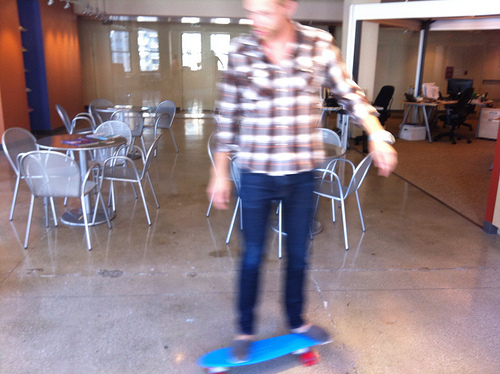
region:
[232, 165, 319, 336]
pair of blue jeans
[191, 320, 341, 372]
blue skateboard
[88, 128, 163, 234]
silver straight back chair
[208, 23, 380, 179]
brown and white plaid long sleeve shirt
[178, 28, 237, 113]
two windows on white doors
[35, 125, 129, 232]
round silver table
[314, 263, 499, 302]
tan square shaped tile on the floor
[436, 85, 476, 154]
black rolling chair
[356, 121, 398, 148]
bracelet on person's wrist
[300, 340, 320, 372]
red wheel on bottom of skateboard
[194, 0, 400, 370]
Man riding a skateboard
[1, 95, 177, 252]
Empty chairs and tables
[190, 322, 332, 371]
A bright blue skateboard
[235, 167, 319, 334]
A pair of blue jeans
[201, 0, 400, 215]
The man appears blurry in motion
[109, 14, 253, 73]
Light coming from windows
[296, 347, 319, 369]
Red wheel of a skateboard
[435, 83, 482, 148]
A black office chair with wheels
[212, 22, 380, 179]
A brown and white checkered shirt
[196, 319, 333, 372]
Two feet on a skateboard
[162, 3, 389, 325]
man on a board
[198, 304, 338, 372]
board under the man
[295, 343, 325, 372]
wheel on the board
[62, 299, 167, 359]
floor next to the board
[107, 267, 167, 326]
line on the ground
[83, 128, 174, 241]
silver chair next to table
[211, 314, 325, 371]
blue top of board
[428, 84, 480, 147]
black chair in the background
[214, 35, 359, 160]
shirt on the man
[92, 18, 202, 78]
windows in the background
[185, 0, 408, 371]
blurry dude on blurry blue 'board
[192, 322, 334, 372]
skateboard is bright blue w/ bright red wheels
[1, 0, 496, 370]
dude skateboarding through indoor/outdoor office/cafe area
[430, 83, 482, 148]
black office chair on wheels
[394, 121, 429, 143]
white file folder box, lid on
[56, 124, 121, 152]
a mess of books on a cafe table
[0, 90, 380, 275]
tables+chairs are all light metal--aluminum, probably--w/ a matte finish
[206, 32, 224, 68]
someone framed in the door window's sunlight, who's either recently left or just arrived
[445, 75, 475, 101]
dark monitor on desk @ back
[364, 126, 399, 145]
a blurry watch above an open hand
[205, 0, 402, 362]
A man on a skateboard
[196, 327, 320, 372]
A blue skateboard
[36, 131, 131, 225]
A round metal table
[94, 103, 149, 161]
A round metal table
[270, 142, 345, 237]
A round metal table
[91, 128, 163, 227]
A silver colored metal chair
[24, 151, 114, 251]
A silver colored metal chair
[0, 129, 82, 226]
A silver colored metal chair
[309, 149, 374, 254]
A silver colored metal chair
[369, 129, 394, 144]
A watch